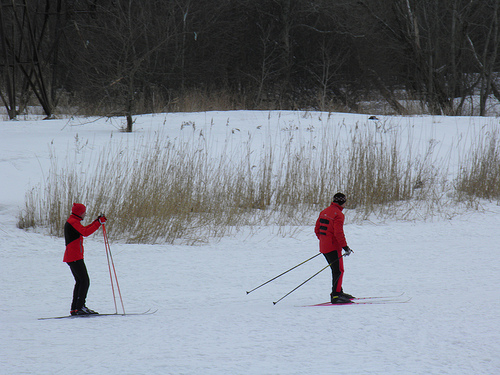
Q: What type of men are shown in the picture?
A: Cross country skiers.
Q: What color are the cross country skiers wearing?
A: Red and black.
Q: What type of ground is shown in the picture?
A: A flat snow covered ground.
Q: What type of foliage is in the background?
A: Leafless trees.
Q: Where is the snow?
A: On the ground.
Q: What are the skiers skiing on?
A: Snow.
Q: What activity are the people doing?
A: Skiing.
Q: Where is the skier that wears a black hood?
A: The one in front.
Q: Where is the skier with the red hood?
A: Behind the skier in front.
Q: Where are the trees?
A: In the distance.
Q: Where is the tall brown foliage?
A: Between the skiers and the trees.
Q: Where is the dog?
A: There isn't a dog.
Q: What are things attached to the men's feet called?
A: Skis.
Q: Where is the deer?
A: None in the picture.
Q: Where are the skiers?
A: Trail.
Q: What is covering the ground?
A: Snow.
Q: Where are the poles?
A: Skiers hands.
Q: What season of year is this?
A: Winter.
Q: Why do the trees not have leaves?
A: Winter.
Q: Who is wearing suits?
A: Skiers.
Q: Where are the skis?
A: Feet.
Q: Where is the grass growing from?
A: Snow.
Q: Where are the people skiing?
A: Field.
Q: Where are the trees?
A: Edge of field.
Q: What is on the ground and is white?
A: Snow.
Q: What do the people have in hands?
A: Poles.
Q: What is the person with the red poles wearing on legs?
A: Black pants.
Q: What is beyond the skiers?
A: Tall grass.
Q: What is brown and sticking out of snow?
A: The tall grass.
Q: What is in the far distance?
A: Trees.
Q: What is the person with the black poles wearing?
A: A red outfit.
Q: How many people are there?
A: 2.